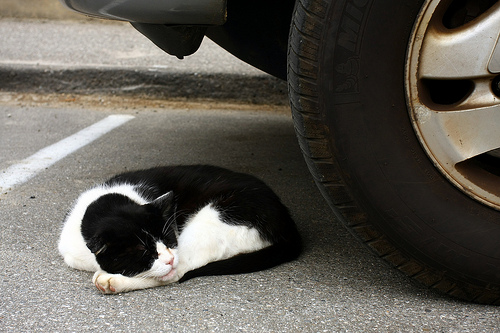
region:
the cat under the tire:
[60, 161, 301, 293]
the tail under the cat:
[180, 241, 302, 283]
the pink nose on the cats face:
[166, 258, 176, 268]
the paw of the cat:
[89, 270, 130, 300]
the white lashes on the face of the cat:
[164, 205, 189, 232]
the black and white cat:
[57, 161, 292, 300]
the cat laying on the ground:
[54, 147, 305, 296]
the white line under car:
[8, 110, 160, 166]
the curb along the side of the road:
[0, 59, 252, 107]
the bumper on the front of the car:
[61, 0, 228, 27]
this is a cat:
[58, 157, 295, 292]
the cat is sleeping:
[40, 163, 290, 295]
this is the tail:
[233, 237, 288, 264]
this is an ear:
[145, 187, 177, 212]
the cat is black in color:
[192, 173, 226, 195]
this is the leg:
[88, 269, 123, 294]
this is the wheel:
[300, 27, 384, 138]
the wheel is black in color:
[306, 26, 401, 128]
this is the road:
[3, 107, 84, 171]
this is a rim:
[414, 30, 491, 137]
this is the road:
[118, 105, 179, 140]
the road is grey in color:
[208, 121, 243, 143]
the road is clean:
[150, 110, 193, 133]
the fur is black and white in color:
[198, 195, 238, 237]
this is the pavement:
[161, 58, 206, 92]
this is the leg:
[97, 275, 126, 289]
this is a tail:
[209, 253, 284, 276]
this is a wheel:
[301, 68, 498, 251]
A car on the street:
[66, 2, 497, 302]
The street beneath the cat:
[0, 92, 499, 332]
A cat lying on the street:
[62, 164, 299, 294]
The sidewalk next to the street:
[0, 20, 286, 101]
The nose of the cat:
[166, 252, 173, 264]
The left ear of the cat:
[143, 192, 172, 219]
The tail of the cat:
[188, 244, 290, 278]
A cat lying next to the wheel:
[58, 165, 298, 294]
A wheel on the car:
[290, 2, 499, 304]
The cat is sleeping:
[56, 166, 301, 296]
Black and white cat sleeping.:
[56, 163, 301, 293]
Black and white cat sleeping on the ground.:
[56, 164, 303, 292]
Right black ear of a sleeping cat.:
[86, 232, 108, 256]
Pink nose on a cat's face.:
[166, 256, 176, 268]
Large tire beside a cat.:
[288, 1, 498, 306]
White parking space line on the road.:
[1, 111, 138, 194]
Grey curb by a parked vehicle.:
[2, 14, 282, 96]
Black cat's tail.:
[178, 238, 299, 283]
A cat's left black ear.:
[141, 191, 174, 218]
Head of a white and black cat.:
[91, 202, 181, 284]